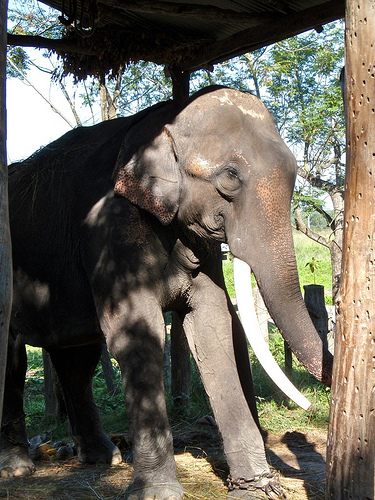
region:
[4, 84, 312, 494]
large gray bull elephant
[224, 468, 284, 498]
chain around elephant's foot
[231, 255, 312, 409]
long ivory elephant tusk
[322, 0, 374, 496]
tall brown vertical tree trunk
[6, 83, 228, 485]
shadow of tree on back of elephant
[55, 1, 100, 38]
ropes hanging from ceiling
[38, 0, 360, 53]
tin roof over elephant enclosure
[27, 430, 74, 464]
pile of elephant feces on the ground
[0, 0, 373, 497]
building support beams are made of wood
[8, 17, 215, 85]
dead brown leaves on a branch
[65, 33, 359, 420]
a elphants standing outside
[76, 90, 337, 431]
an elephant standing up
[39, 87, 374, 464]
an elephant that is chained up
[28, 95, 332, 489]
a large elephant chained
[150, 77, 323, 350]
an elephant with long tusks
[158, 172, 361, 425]
an elephant with long white tusks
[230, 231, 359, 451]
long white elephant tusks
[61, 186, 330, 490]
a elephant in an area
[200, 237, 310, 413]
the tusk is white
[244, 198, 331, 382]
the trunk is thick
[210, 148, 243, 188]
the eye is small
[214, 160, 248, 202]
the eye is open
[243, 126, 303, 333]
the trunk is discolored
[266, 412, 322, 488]
the shadow on the floor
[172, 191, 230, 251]
the skin is wrinkled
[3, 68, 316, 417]
the elephant is standing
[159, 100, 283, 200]
the sun is on the elephants face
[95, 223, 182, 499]
this is a leg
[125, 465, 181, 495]
this is a foot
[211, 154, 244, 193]
this is an eye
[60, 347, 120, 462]
this is a leg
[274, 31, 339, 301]
this is a tree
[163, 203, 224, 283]
this is a neck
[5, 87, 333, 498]
A young elephant standing still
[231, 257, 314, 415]
A shiny white tusk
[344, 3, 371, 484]
A log with many holes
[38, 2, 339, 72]
A thatched hut roof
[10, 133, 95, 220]
Hay sprinkled on the elephant's back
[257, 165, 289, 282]
Brown patches and spots on the trunk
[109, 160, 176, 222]
Brown patches and spots on the ear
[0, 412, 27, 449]
Chains around the elephant's leg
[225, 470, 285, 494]
Chains on the elephant's front left foot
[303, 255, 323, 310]
A sprouting plant from a pot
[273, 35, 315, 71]
green tree leaves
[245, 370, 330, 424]
a section of green grass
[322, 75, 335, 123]
green leaves on the tree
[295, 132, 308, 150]
green leaves on the tree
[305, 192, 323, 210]
green leaves on the tree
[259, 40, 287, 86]
green leaves on the tree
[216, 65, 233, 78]
green leaves on the tree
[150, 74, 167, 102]
green leaves on the tree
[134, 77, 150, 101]
green leaves on the tree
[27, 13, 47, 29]
green leaves on the tree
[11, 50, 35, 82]
green leaves on the tree